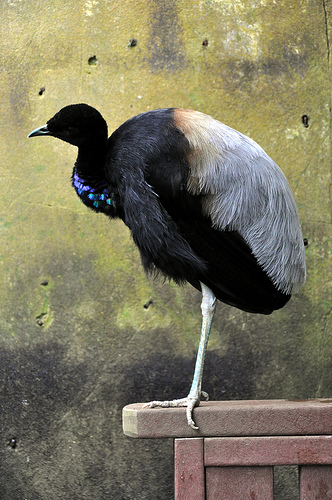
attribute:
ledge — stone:
[143, 361, 318, 448]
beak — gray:
[13, 110, 53, 144]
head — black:
[28, 102, 109, 148]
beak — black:
[25, 121, 50, 137]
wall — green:
[2, 204, 152, 315]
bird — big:
[19, 63, 314, 440]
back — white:
[171, 106, 308, 296]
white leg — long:
[142, 279, 217, 429]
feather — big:
[114, 170, 206, 276]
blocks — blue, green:
[70, 168, 117, 221]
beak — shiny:
[28, 124, 46, 139]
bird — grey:
[26, 100, 311, 424]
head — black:
[48, 102, 100, 145]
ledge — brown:
[108, 394, 331, 495]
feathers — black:
[150, 181, 285, 316]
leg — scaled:
[151, 284, 224, 430]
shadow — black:
[157, 31, 265, 93]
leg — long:
[194, 279, 216, 398]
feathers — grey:
[170, 102, 309, 298]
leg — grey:
[139, 282, 220, 428]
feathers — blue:
[70, 165, 117, 210]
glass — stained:
[3, 11, 315, 102]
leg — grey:
[142, 280, 216, 430]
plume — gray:
[169, 107, 303, 298]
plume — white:
[216, 129, 302, 292]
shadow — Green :
[111, 288, 300, 429]